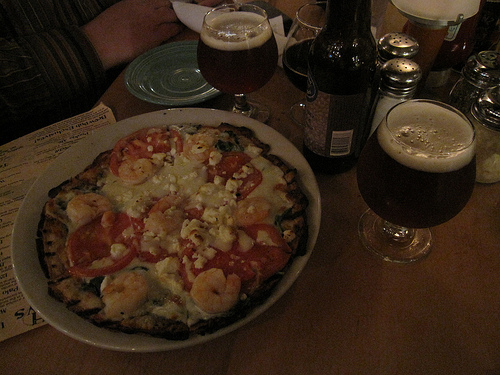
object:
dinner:
[32, 122, 311, 341]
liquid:
[307, 3, 376, 174]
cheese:
[153, 161, 207, 196]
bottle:
[300, 0, 375, 175]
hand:
[75, 1, 194, 71]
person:
[0, 0, 193, 119]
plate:
[11, 106, 322, 353]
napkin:
[167, 0, 296, 69]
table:
[0, 0, 500, 375]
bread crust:
[130, 326, 188, 342]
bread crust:
[197, 275, 281, 336]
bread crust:
[48, 152, 105, 197]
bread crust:
[35, 219, 73, 301]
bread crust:
[283, 170, 308, 257]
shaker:
[448, 49, 500, 112]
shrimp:
[191, 267, 240, 313]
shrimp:
[101, 268, 147, 317]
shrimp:
[67, 189, 114, 228]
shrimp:
[143, 193, 179, 237]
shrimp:
[238, 192, 268, 227]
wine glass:
[358, 99, 479, 230]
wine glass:
[193, 4, 282, 120]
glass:
[353, 95, 480, 266]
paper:
[0, 103, 118, 345]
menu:
[1, 101, 132, 343]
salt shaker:
[381, 55, 423, 101]